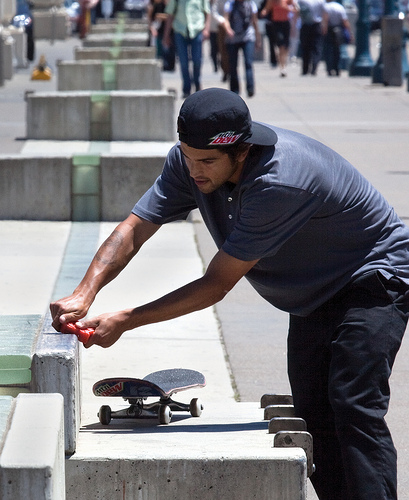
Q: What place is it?
A: It is a sidewalk.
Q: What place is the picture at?
A: It is at the sidewalk.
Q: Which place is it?
A: It is a sidewalk.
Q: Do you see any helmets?
A: No, there are no helmets.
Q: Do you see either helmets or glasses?
A: No, there are no helmets or glasses.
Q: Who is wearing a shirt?
A: The man is wearing a shirt.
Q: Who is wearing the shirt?
A: The man is wearing a shirt.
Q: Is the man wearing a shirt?
A: Yes, the man is wearing a shirt.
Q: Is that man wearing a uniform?
A: No, the man is wearing a shirt.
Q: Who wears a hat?
A: The man wears a hat.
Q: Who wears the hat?
A: The man wears a hat.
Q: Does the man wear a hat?
A: Yes, the man wears a hat.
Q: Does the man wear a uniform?
A: No, the man wears a hat.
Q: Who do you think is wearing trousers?
A: The man is wearing trousers.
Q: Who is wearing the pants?
A: The man is wearing trousers.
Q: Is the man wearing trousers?
A: Yes, the man is wearing trousers.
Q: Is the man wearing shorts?
A: No, the man is wearing trousers.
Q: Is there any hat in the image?
A: Yes, there is a hat.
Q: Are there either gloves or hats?
A: Yes, there is a hat.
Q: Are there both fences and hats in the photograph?
A: No, there is a hat but no fences.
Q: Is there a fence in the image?
A: No, there are no fences.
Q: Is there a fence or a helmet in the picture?
A: No, there are no fences or helmets.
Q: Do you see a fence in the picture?
A: No, there are no fences.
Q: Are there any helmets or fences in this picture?
A: No, there are no fences or helmets.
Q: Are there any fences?
A: No, there are no fences.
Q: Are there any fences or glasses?
A: No, there are no fences or glasses.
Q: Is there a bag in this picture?
A: No, there are no bags.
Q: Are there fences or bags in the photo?
A: No, there are no bags or fences.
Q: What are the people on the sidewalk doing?
A: The people are walking.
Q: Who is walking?
A: The people are walking.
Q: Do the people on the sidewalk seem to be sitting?
A: No, the people are walking.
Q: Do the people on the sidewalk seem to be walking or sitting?
A: The people are walking.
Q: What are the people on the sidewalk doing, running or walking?
A: The people are walking.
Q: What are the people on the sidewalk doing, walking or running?
A: The people are walking.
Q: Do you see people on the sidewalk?
A: Yes, there are people on the sidewalk.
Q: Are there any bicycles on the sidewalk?
A: No, there are people on the sidewalk.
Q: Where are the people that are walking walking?
A: The people are walking on the sidewalk.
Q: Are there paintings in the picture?
A: No, there are no paintings.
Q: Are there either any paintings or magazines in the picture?
A: No, there are no paintings or magazines.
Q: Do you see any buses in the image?
A: No, there are no buses.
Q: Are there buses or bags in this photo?
A: No, there are no buses or bags.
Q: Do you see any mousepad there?
A: No, there are no mouse pads.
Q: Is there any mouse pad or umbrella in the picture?
A: No, there are no mouse pads or umbrellas.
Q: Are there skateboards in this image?
A: Yes, there is a skateboard.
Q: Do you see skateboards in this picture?
A: Yes, there is a skateboard.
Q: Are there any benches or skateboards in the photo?
A: Yes, there is a skateboard.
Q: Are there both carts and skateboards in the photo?
A: No, there is a skateboard but no carts.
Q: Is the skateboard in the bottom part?
A: Yes, the skateboard is in the bottom of the image.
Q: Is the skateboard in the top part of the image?
A: No, the skateboard is in the bottom of the image.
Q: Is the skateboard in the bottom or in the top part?
A: The skateboard is in the bottom of the image.